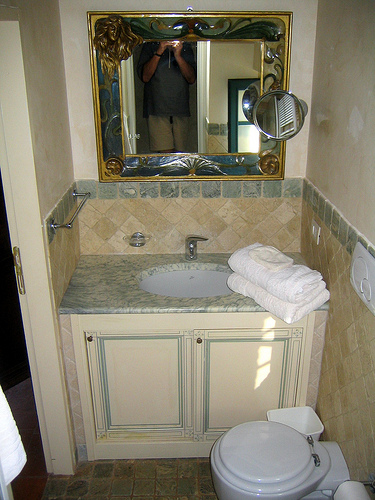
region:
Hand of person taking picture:
[158, 39, 168, 50]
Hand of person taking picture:
[170, 41, 184, 52]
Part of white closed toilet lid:
[237, 440, 271, 466]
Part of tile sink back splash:
[147, 207, 183, 230]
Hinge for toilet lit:
[306, 434, 326, 470]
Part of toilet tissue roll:
[322, 477, 373, 498]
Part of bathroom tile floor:
[103, 477, 152, 494]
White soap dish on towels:
[250, 237, 293, 273]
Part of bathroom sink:
[164, 278, 181, 293]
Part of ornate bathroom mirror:
[93, 12, 135, 60]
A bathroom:
[1, 5, 372, 494]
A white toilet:
[206, 414, 354, 498]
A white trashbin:
[266, 401, 327, 439]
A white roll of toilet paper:
[335, 474, 368, 498]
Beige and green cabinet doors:
[65, 315, 310, 459]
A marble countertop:
[65, 249, 329, 315]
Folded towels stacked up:
[226, 244, 331, 319]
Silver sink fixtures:
[180, 233, 210, 260]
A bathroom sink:
[137, 230, 248, 303]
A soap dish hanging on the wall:
[118, 228, 153, 248]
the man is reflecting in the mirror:
[156, 60, 185, 91]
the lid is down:
[249, 431, 277, 472]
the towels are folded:
[254, 259, 285, 286]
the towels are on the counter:
[241, 283, 252, 306]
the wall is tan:
[334, 326, 355, 362]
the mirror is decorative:
[91, 17, 267, 37]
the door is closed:
[189, 326, 211, 366]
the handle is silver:
[70, 206, 84, 223]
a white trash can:
[261, 400, 330, 442]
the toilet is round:
[195, 417, 347, 498]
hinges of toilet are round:
[302, 433, 327, 467]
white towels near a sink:
[220, 233, 331, 332]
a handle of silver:
[46, 180, 96, 237]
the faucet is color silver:
[183, 242, 201, 263]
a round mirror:
[247, 84, 314, 146]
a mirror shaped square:
[80, 6, 296, 188]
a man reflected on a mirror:
[128, 38, 201, 153]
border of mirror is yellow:
[80, 5, 295, 187]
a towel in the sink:
[230, 241, 316, 316]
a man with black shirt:
[145, 63, 201, 114]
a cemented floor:
[119, 480, 139, 498]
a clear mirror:
[148, 66, 242, 143]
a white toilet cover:
[226, 444, 296, 488]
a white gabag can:
[287, 407, 325, 442]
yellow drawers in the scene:
[99, 334, 180, 417]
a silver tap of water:
[175, 236, 208, 262]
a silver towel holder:
[54, 216, 90, 236]